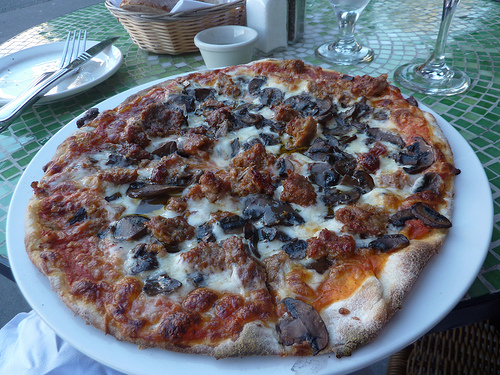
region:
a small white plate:
[0, 37, 119, 111]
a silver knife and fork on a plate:
[0, 37, 118, 127]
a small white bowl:
[192, 23, 263, 65]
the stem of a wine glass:
[396, 6, 473, 110]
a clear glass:
[314, 8, 384, 70]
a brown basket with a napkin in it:
[116, 3, 201, 60]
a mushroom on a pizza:
[273, 295, 338, 357]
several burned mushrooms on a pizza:
[296, 97, 381, 213]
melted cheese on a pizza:
[148, 194, 243, 304]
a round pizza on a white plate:
[0, 92, 445, 309]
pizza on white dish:
[1, 51, 498, 373]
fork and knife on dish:
[5, 17, 127, 126]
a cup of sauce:
[188, 22, 270, 70]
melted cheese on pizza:
[85, 75, 403, 301]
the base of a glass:
[388, 2, 481, 102]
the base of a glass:
[305, 3, 384, 70]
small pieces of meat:
[226, 135, 277, 199]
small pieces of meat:
[273, 98, 317, 154]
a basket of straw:
[95, 0, 245, 60]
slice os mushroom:
[268, 293, 335, 356]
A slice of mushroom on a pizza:
[277, 298, 329, 355]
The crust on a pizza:
[326, 224, 437, 347]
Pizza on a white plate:
[3, 61, 493, 371]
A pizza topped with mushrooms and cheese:
[113, 86, 367, 258]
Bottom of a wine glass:
[396, 8, 473, 95]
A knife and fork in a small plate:
[1, 28, 117, 135]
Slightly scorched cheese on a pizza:
[156, 283, 214, 344]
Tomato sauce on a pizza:
[44, 202, 119, 292]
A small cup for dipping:
[193, 23, 255, 67]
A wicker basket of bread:
[104, 1, 246, 59]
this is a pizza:
[3, 27, 497, 370]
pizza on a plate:
[11, 30, 494, 372]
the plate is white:
[16, 27, 498, 374]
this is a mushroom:
[265, 280, 337, 362]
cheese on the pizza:
[86, 156, 242, 298]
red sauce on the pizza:
[51, 231, 133, 301]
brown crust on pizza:
[319, 235, 444, 357]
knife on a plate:
[0, 32, 128, 120]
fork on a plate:
[0, 22, 94, 127]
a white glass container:
[165, 15, 274, 80]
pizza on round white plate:
[2, 57, 494, 374]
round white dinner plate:
[2, 56, 498, 373]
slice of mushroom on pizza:
[407, 197, 456, 231]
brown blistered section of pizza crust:
[324, 241, 437, 361]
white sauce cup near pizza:
[190, 19, 260, 71]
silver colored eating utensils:
[0, 32, 125, 137]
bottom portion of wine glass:
[395, 2, 482, 100]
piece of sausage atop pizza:
[145, 211, 200, 249]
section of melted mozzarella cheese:
[153, 254, 190, 286]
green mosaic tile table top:
[5, 3, 497, 319]